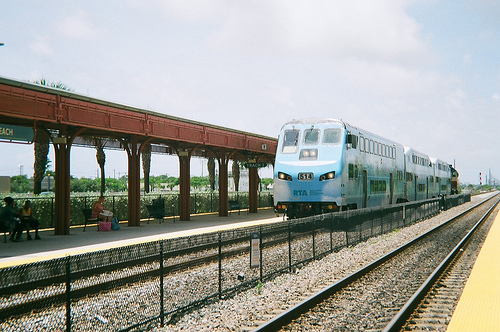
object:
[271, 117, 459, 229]
train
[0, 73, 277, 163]
bridge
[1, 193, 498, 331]
gravel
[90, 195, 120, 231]
people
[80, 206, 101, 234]
bench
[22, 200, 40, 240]
people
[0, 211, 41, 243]
bench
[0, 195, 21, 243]
people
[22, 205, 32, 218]
shirt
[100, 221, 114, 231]
bag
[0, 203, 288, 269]
ground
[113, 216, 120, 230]
bag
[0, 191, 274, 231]
fence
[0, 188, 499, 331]
track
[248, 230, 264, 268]
sign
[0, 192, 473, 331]
fence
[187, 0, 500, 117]
sky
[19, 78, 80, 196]
trees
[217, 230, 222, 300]
post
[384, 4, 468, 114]
clouds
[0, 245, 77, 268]
paint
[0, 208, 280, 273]
platform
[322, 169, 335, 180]
light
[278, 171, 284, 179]
light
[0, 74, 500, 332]
station